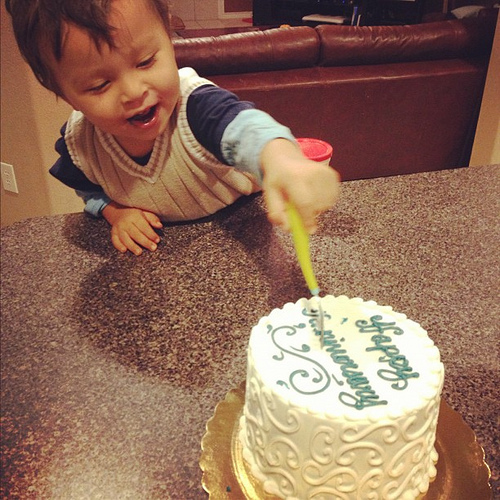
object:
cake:
[231, 295, 445, 500]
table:
[0, 165, 500, 499]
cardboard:
[198, 379, 494, 500]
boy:
[4, 0, 339, 256]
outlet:
[0, 162, 18, 194]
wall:
[0, 0, 86, 226]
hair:
[7, 0, 172, 103]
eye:
[135, 49, 159, 69]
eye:
[85, 80, 111, 95]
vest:
[64, 67, 262, 221]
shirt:
[75, 86, 298, 217]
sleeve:
[186, 84, 255, 165]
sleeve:
[49, 121, 103, 192]